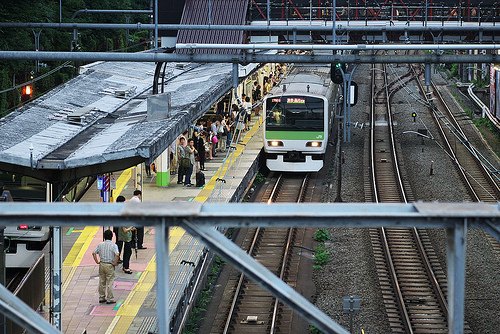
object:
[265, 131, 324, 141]
stripe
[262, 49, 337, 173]
train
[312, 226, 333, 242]
weeds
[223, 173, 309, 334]
train tracks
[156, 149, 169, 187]
pole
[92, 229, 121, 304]
man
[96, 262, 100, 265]
hands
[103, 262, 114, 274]
hips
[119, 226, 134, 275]
woman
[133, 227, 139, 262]
umbrella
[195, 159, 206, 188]
rolling bag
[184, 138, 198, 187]
man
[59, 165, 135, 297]
line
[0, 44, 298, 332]
platform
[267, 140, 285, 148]
light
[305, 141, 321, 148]
light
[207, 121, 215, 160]
woman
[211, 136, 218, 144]
purse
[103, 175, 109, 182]
stripes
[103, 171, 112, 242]
pole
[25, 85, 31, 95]
lamp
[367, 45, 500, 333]
railway line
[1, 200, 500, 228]
metal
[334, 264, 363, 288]
rocks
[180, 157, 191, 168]
bag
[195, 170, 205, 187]
bag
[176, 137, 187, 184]
person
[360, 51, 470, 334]
train tracks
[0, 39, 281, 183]
roof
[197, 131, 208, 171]
people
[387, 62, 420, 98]
curve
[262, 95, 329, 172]
front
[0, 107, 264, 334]
ground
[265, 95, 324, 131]
windshield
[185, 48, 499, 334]
ground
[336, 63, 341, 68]
light